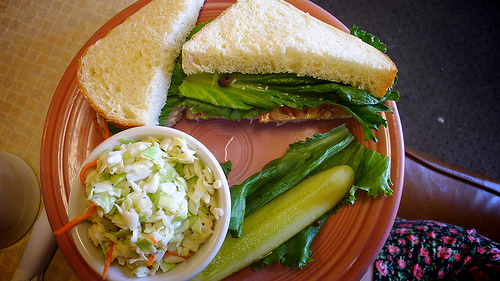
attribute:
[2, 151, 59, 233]
cup — small, empty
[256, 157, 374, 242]
pickle — green, long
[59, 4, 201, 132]
sandwich — white, triangle, horizonal, plate, cut, halves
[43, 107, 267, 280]
bowl — white, next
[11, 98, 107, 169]
plate — orange, top, colored, red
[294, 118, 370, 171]
lettuce — top, under, green, leaf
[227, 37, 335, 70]
bread — white, next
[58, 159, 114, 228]
carrot — mixed, piece, stick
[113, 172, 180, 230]
cabbage — chopped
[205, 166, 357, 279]
spear — pickel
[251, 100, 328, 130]
pail — garbage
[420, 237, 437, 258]
flower — green, pink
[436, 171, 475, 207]
couch — brown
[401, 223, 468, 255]
dress — flowered